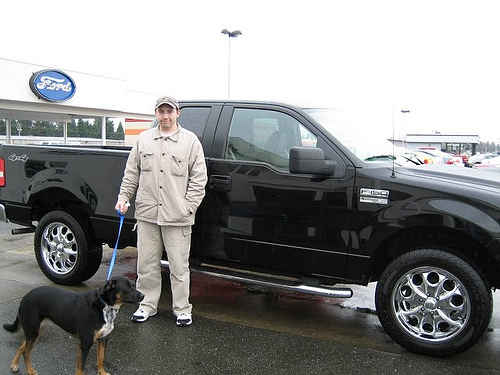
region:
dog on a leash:
[9, 262, 135, 369]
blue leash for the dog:
[99, 241, 129, 281]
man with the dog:
[80, 80, 208, 346]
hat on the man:
[147, 91, 182, 114]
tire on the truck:
[382, 248, 472, 350]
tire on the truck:
[18, 212, 105, 290]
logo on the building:
[27, 69, 77, 102]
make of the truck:
[334, 178, 397, 208]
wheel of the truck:
[398, 278, 458, 330]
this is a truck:
[108, 77, 226, 344]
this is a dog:
[19, 233, 151, 372]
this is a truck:
[5, 67, 496, 347]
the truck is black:
[13, 70, 497, 374]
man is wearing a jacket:
[123, 113, 213, 230]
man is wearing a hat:
[140, 75, 196, 132]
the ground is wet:
[216, 280, 351, 368]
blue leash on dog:
[86, 190, 147, 293]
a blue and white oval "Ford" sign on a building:
[28, 66, 80, 103]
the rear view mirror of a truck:
[283, 143, 338, 181]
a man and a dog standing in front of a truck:
[5, 91, 207, 371]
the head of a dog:
[96, 270, 151, 308]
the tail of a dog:
[1, 293, 23, 337]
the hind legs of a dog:
[10, 316, 41, 373]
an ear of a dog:
[97, 275, 119, 295]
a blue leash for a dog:
[102, 211, 127, 281]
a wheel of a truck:
[373, 246, 494, 356]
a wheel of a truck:
[29, 211, 103, 283]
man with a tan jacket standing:
[111, 89, 218, 336]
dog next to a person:
[1, 269, 150, 374]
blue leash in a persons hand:
[98, 196, 135, 295]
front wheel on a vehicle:
[366, 242, 497, 365]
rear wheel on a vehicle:
[26, 206, 111, 288]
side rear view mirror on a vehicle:
[283, 142, 341, 182]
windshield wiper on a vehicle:
[360, 149, 409, 171]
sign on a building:
[25, 65, 80, 106]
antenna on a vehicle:
[386, 91, 401, 184]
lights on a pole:
[215, 20, 249, 51]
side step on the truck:
[157, 257, 351, 297]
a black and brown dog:
[7, 275, 143, 373]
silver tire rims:
[389, 266, 469, 342]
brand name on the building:
[30, 68, 75, 100]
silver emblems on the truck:
[358, 186, 388, 205]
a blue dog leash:
[105, 210, 123, 282]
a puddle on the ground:
[339, 303, 374, 314]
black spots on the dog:
[105, 306, 118, 326]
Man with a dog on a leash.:
[3, 94, 208, 373]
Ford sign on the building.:
[30, 67, 77, 101]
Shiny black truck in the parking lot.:
[0, 97, 497, 355]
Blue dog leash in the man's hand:
[105, 196, 128, 288]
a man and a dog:
[1, 96, 203, 373]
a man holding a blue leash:
[1, 94, 227, 374]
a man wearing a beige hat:
[116, 95, 208, 325]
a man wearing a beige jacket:
[115, 96, 205, 322]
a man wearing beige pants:
[116, 94, 210, 326]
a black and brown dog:
[3, 271, 148, 372]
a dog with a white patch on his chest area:
[3, 274, 148, 374]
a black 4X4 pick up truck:
[1, 98, 499, 359]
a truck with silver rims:
[3, 95, 499, 352]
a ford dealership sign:
[31, 66, 79, 107]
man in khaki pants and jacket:
[139, 94, 215, 332]